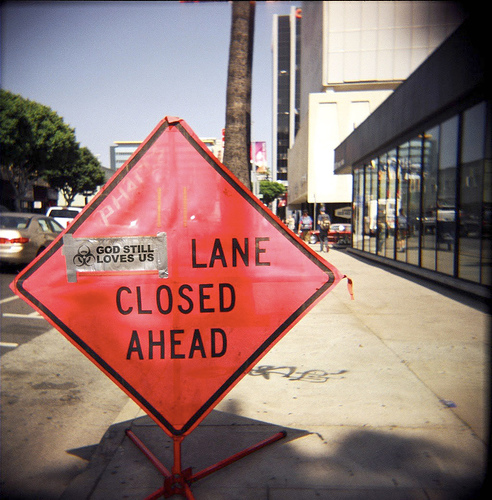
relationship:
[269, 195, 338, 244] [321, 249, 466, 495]
people walking at sidewalk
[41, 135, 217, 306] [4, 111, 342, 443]
sign taped to a sign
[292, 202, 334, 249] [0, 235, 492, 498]
people walking on sidewalk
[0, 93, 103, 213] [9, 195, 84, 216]
trees on sidewalk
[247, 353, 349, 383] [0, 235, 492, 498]
graffiti on sidewalk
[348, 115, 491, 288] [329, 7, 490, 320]
windows on a building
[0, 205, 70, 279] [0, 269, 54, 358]
car on strteet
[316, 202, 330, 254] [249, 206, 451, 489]
people walking on sidewalk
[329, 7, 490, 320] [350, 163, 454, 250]
building with windows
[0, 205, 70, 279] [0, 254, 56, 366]
car on road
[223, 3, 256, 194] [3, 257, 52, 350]
tree next to street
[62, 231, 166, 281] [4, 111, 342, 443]
sticker on sign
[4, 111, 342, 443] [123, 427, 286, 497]
sign on base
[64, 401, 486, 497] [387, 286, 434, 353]
shadows on sidewalk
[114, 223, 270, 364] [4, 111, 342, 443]
lettering on sign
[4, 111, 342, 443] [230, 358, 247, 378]
sign with border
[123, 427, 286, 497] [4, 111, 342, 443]
base of sign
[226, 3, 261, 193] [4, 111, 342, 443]
trunk behind sign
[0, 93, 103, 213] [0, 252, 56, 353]
trees along street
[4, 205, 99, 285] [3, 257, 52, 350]
car driving down street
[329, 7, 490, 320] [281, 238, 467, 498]
building alongside sidewalk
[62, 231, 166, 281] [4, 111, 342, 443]
sticker stuck on sign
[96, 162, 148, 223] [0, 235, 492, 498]
graffiti on sidewalk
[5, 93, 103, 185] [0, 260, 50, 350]
trees across street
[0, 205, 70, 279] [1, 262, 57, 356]
car in road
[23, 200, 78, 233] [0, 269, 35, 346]
truck in road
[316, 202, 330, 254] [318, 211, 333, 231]
people with backpack